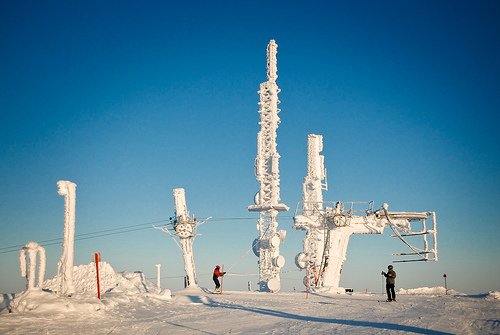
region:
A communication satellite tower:
[251, 38, 283, 293]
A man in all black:
[381, 263, 398, 300]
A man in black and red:
[211, 265, 225, 289]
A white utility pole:
[166, 185, 208, 291]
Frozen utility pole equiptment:
[295, 131, 448, 293]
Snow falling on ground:
[4, 285, 497, 330]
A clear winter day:
[4, 5, 488, 332]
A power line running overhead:
[0, 215, 172, 256]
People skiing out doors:
[188, 252, 432, 309]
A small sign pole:
[438, 270, 450, 295]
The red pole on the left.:
[90, 250, 105, 296]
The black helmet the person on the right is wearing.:
[385, 263, 391, 268]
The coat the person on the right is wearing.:
[385, 270, 395, 285]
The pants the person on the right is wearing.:
[385, 283, 396, 299]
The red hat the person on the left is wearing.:
[216, 264, 220, 269]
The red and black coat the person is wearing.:
[212, 270, 220, 279]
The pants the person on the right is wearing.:
[212, 275, 219, 287]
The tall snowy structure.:
[238, 38, 288, 291]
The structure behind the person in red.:
[152, 189, 213, 299]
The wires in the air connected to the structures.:
[4, 203, 349, 258]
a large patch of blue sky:
[0, 0, 499, 296]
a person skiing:
[376, 264, 405, 301]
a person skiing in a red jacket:
[207, 264, 229, 294]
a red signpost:
[91, 250, 101, 297]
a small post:
[442, 273, 447, 293]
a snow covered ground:
[0, 285, 499, 333]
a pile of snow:
[7, 260, 170, 310]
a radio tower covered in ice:
[246, 38, 289, 291]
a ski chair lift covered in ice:
[0, 187, 437, 290]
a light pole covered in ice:
[55, 179, 76, 296]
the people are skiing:
[210, 260, 397, 302]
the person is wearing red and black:
[213, 261, 225, 293]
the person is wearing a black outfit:
[381, 265, 398, 302]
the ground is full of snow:
[0, 262, 499, 332]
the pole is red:
[93, 252, 103, 297]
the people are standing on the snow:
[0, 260, 498, 332]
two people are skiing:
[211, 262, 398, 301]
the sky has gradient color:
[0, 2, 497, 293]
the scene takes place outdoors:
[1, 0, 499, 333]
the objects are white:
[19, 40, 440, 293]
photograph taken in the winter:
[18, 28, 471, 313]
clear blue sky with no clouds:
[61, 23, 187, 132]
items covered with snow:
[17, 41, 439, 307]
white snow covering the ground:
[175, 300, 482, 324]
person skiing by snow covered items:
[361, 260, 410, 301]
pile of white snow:
[12, 254, 124, 310]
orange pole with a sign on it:
[92, 244, 107, 300]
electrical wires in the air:
[12, 187, 425, 262]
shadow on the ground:
[173, 270, 450, 326]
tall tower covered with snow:
[242, 38, 284, 300]